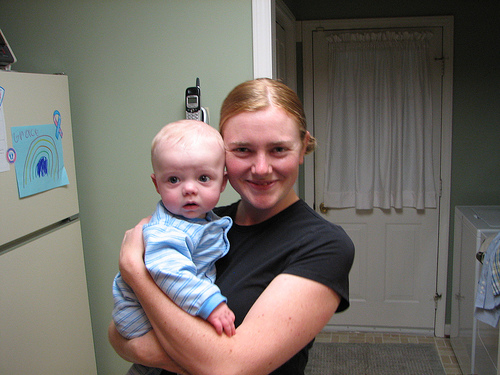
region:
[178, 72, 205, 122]
black and grey telephone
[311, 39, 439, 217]
white curtains on window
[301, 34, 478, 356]
covered window on white door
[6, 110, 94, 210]
drawing on white refridgerator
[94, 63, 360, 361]
woman holding a baby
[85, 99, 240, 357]
baby wearing a onesie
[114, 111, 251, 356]
baby wearing a blue outfit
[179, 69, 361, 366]
woman wearing a black shirt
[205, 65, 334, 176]
woman with blonde hair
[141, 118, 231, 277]
baby looking startled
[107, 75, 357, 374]
woman smilingly holding a baby boy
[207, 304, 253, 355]
baby's hand is touching woman's arm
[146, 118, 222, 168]
baby has pale blonde hair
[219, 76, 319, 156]
woman's blonde hair is pulled back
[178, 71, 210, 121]
cordless phone on the wall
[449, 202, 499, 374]
washer and dryer partially visible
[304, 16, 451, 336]
door thrown partly into shadow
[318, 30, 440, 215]
white curtain across top section of door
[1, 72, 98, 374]
drawing of a rainbow on a refrigerator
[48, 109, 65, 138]
magnet shaped like a ribbon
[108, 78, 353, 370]
a woman holding a baby in her hands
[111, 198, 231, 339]
a baby wearing a white and blue stripes pajama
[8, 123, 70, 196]
a kid's drawing on a fridge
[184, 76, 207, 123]
a landline phone on the wall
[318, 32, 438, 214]
white drapes on a window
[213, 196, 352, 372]
a woman wearing a black shirt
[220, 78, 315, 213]
a woman with strawberry blonde hair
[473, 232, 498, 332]
a wash dishing cloth on a counter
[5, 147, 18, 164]
a round magnet on a fridge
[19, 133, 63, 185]
drawing of a rainbow on blue paper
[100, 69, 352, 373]
Young woman holding a baby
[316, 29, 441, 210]
Beige curtain on a curtain rod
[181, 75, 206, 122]
A phone with a black antenna in a wall charger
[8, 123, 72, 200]
Child's drawing on light blue construction paper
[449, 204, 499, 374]
Front portion of a front loading washing machine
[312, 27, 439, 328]
Beige door with a curtain on it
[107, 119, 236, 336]
Blonde baby in a blue striped outfit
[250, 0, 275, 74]
Small strip of white wall molding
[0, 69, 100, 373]
Part of a beige refrigerator with some stuff stuck to it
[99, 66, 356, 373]
Baby boy being held by a smiling woman with red hair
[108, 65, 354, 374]
Woman in black shirt holding baby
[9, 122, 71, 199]
Picture of rainbow on refrigerator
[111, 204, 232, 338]
Blue stripes on baby's onesie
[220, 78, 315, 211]
Woman's hair parted on one side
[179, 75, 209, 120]
Black and silver cordless phone on wall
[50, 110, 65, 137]
Magnet on front of refrigerator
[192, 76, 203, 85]
Antenna on cordless phone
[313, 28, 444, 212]
White curtain over window on door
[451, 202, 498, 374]
White washing machine in corner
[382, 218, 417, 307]
White panel on back door